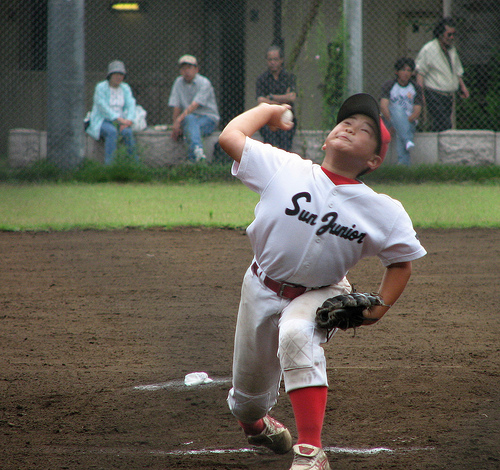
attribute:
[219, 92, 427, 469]
boy — small, playing baseball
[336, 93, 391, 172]
cap — red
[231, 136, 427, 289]
shirt — white, short sleeve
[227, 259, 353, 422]
pants — white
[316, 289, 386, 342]
glove — black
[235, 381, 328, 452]
socks — long, red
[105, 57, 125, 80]
hat — gray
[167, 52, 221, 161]
man — sitting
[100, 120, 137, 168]
jeans — blue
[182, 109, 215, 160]
jeans — blue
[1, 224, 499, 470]
field — dirt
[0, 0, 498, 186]
fence — chain link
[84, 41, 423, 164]
spectators — sitting, watching game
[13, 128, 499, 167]
wall — concrete, white, stone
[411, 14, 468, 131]
man — walking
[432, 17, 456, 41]
hair — dark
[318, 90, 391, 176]
head — raised up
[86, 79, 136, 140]
jacket — blue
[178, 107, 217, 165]
legs — crossed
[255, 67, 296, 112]
shirt — black